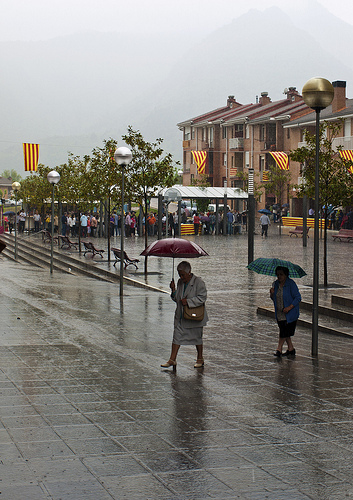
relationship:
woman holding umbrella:
[268, 268, 306, 358] [251, 256, 308, 281]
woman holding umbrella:
[159, 261, 208, 374] [135, 229, 206, 263]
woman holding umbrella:
[159, 261, 208, 374] [136, 240, 207, 257]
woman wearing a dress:
[159, 261, 208, 374] [170, 276, 203, 342]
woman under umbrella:
[159, 261, 208, 374] [139, 232, 209, 284]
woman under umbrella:
[159, 261, 208, 374] [140, 237, 209, 282]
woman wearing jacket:
[159, 261, 208, 374] [169, 271, 210, 331]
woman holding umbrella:
[268, 266, 302, 358] [245, 257, 306, 279]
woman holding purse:
[159, 261, 208, 374] [181, 299, 205, 322]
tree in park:
[322, 143, 330, 287] [26, 178, 351, 290]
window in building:
[222, 153, 226, 166] [175, 79, 350, 229]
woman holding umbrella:
[159, 261, 208, 374] [142, 235, 210, 263]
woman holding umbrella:
[260, 214, 271, 235] [256, 208, 273, 215]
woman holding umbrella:
[159, 261, 208, 374] [136, 234, 209, 259]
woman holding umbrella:
[159, 261, 208, 374] [138, 232, 218, 293]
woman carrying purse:
[159, 261, 208, 374] [173, 291, 209, 323]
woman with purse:
[151, 261, 220, 379] [178, 296, 207, 322]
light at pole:
[112, 145, 132, 170] [228, 162, 269, 271]